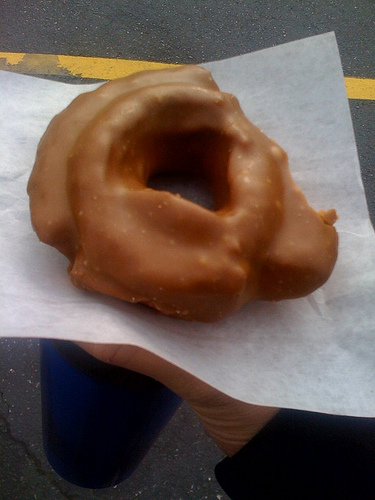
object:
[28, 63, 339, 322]
doughnut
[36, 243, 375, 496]
person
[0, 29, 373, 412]
paper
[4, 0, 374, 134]
road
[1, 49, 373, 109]
line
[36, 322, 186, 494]
cup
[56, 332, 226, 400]
thumb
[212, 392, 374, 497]
sleeve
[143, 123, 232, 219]
hole